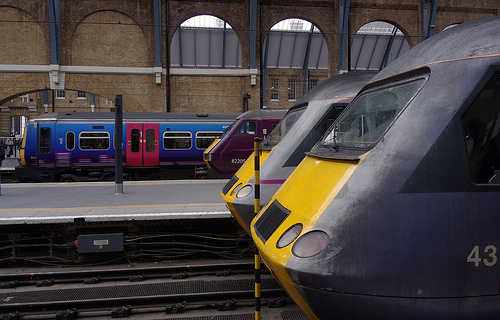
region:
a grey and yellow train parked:
[252, 16, 498, 310]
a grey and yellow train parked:
[220, 65, 372, 250]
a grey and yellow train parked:
[204, 100, 286, 185]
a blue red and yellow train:
[16, 109, 233, 178]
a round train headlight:
[275, 223, 305, 247]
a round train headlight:
[293, 228, 327, 256]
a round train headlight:
[236, 185, 250, 198]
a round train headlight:
[230, 183, 242, 194]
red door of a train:
[125, 122, 142, 165]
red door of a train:
[143, 123, 159, 168]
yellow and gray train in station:
[316, 33, 462, 303]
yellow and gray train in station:
[236, 150, 282, 187]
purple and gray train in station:
[226, 113, 256, 145]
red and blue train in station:
[22, 122, 202, 178]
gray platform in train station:
[10, 183, 207, 200]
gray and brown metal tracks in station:
[10, 266, 238, 305]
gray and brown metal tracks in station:
[13, 225, 238, 255]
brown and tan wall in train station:
[7, 20, 44, 58]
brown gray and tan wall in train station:
[83, 22, 140, 95]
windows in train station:
[175, 15, 377, 71]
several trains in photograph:
[12, 70, 442, 308]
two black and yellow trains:
[204, 20, 409, 310]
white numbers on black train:
[422, 218, 497, 273]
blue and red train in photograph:
[10, 95, 211, 187]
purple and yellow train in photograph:
[194, 110, 265, 171]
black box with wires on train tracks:
[61, 208, 145, 275]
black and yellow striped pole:
[225, 90, 293, 318]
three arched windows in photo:
[171, 5, 416, 75]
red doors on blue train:
[110, 117, 184, 177]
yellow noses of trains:
[226, 153, 352, 274]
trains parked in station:
[212, 84, 499, 301]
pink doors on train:
[116, 115, 164, 177]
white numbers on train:
[459, 222, 496, 281]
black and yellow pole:
[244, 127, 271, 317]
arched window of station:
[163, 4, 253, 76]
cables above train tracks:
[132, 229, 225, 282]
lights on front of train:
[276, 218, 348, 268]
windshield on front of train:
[309, 62, 436, 163]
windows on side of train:
[156, 123, 224, 155]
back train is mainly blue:
[22, 120, 227, 167]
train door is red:
[125, 121, 160, 168]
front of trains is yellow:
[224, 148, 368, 317]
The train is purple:
[201, 112, 282, 176]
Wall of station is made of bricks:
[2, 3, 497, 117]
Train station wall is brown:
[2, 1, 497, 113]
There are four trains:
[20, 18, 497, 309]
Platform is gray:
[0, 183, 245, 218]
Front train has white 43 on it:
[466, 242, 498, 271]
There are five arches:
[2, 11, 421, 73]